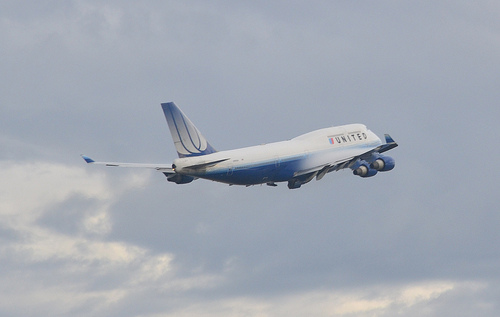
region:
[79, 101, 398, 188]
Plane from United Airlines in flight.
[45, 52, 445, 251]
the plane is mostly white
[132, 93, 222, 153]
the tail is grey with blue in it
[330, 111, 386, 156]
the brand is united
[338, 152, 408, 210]
the engines are blue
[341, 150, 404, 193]
2 engines under the wing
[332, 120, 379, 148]
the letters are black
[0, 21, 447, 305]
the sky is overcast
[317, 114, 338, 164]
red and blue symbol next to the word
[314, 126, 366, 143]
windows on the side of the plane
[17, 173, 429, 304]
the clouds are grey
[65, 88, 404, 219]
this is a plane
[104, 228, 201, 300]
the sky is clear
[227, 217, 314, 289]
the sky is clear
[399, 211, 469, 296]
the sky is clear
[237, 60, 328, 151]
the sky is clear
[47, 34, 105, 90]
the sky is clear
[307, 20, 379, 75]
the sky is clear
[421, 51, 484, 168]
the sky is clear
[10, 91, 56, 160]
the sky is clear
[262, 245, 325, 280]
the sky is clear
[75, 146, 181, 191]
Left wing of plane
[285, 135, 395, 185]
Right wing of plane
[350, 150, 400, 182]
Right engines of plane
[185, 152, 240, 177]
Right tail wing of plane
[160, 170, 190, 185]
Left engines of plane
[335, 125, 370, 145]
Word "United" on plane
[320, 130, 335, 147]
United symbol on plane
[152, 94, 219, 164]
Tail of plane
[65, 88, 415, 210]
Blue and white plane flying in the sky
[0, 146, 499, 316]
White clouds in the sky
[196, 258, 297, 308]
a section of the sky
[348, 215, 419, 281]
a section of the sky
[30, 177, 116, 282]
a section of the sky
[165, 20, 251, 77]
a section of the sky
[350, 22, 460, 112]
a section of the sky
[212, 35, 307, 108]
a section of the sky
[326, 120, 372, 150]
the writing on the plane